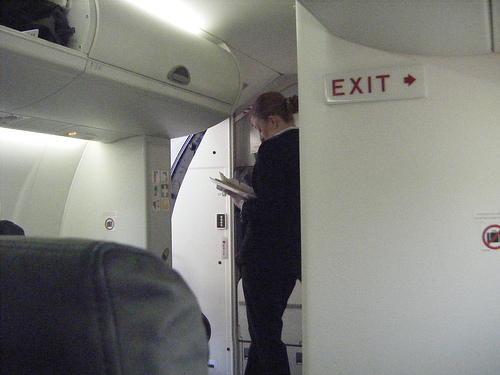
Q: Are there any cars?
A: No, there are no cars.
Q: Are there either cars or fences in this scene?
A: No, there are no cars or fences.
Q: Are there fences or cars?
A: No, there are no cars or fences.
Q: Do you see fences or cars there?
A: No, there are no cars or fences.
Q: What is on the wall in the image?
A: The sign is on the wall.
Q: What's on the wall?
A: The sign is on the wall.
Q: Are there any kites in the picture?
A: No, there are no kites.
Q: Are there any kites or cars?
A: No, there are no kites or cars.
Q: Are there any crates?
A: No, there are no crates.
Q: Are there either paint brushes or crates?
A: No, there are no crates or paint brushes.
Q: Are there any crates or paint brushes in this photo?
A: No, there are no crates or paint brushes.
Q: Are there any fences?
A: No, there are no fences.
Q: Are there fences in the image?
A: No, there are no fences.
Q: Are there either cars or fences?
A: No, there are no fences or cars.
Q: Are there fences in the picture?
A: No, there are no fences.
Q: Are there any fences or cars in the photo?
A: No, there are no fences or cars.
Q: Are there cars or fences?
A: No, there are no fences or cars.